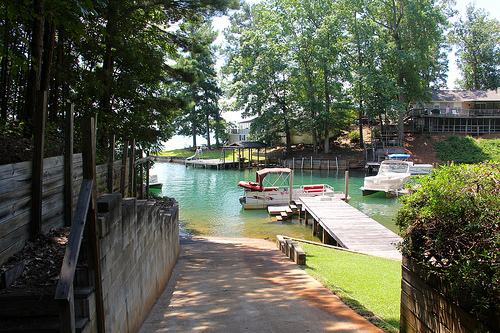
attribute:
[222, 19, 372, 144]
trees — Tall , green 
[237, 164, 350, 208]
boat — docked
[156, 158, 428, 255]
river — blue, brown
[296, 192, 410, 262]
dock — wooden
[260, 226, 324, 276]
stones — small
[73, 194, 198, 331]
wall — stone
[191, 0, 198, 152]
trees — very tall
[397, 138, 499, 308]
hedge — short, green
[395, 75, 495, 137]
building — wooden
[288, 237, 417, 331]
grass — green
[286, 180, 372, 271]
dock — light brown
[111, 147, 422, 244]
lake — beautiful, blue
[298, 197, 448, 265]
dock — wood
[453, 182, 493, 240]
leaves — small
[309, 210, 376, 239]
pier — small, brown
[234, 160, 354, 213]
boat — small, white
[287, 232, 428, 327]
grass — green, short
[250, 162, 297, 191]
canopy — is small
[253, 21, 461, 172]
trees — tall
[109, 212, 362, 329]
shadows — black , Long 